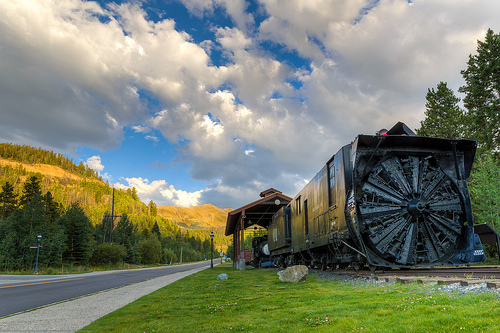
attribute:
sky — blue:
[74, 86, 222, 194]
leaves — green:
[456, 28, 484, 147]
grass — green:
[74, 258, 484, 331]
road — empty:
[4, 244, 216, 315]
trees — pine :
[4, 169, 231, 272]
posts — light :
[17, 236, 200, 271]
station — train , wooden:
[225, 184, 295, 274]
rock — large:
[273, 254, 317, 292]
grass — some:
[254, 288, 334, 312]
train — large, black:
[261, 126, 491, 272]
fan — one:
[358, 146, 475, 269]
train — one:
[244, 130, 481, 270]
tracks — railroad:
[276, 253, 492, 286]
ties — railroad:
[349, 269, 490, 289]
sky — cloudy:
[274, 52, 360, 161]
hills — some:
[8, 145, 213, 249]